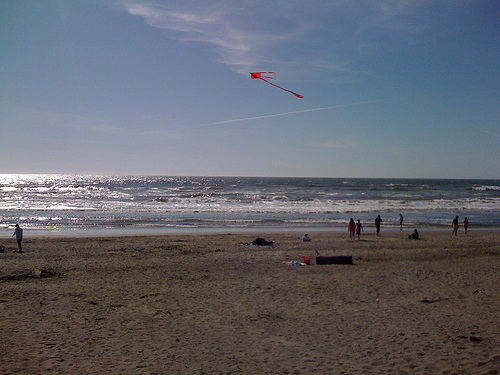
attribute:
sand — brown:
[3, 236, 497, 373]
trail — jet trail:
[206, 100, 345, 132]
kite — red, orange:
[249, 66, 307, 102]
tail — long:
[266, 72, 307, 102]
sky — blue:
[3, 5, 499, 177]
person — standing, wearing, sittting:
[13, 214, 476, 253]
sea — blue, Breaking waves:
[5, 166, 496, 222]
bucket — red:
[301, 254, 312, 264]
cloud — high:
[125, 4, 424, 67]